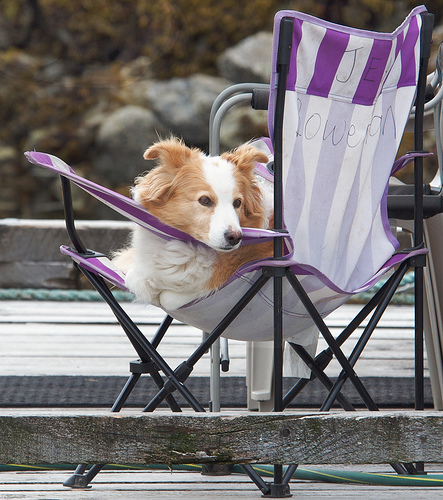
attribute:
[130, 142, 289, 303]
dog — sitting, looking away, furry, laying, brown, white, jackson mingus, reclined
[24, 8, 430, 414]
chair — purple, striped, white, foldable, folding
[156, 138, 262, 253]
head — brown, white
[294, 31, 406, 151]
writing — sharpie, name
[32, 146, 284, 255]
arm rest — black, purple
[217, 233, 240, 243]
nose — black, red, brown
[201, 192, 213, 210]
eye — black, large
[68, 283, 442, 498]
metal poles — black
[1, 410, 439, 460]
post — wooden, worn wood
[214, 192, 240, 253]
nose — white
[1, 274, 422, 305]
rope — green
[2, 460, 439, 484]
hose — yellow, green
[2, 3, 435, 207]
trees — brown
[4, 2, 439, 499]
photo — great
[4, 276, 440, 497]
deck — wooden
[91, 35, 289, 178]
rocks — large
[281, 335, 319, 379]
tag — white